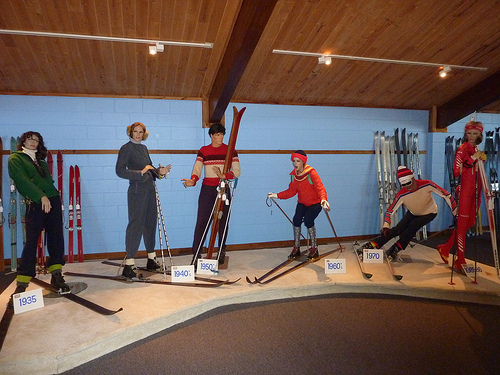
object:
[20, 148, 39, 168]
turtle neck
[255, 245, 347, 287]
skis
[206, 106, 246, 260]
skis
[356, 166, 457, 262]
mannequin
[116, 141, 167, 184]
one piece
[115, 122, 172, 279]
adult mannequin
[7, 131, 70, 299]
adult mannequin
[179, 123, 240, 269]
adult mannequin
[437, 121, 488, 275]
adult mannequin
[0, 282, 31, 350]
skis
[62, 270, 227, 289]
skis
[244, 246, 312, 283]
skis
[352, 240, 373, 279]
skis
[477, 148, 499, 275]
skis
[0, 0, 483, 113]
ceiling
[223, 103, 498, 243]
wall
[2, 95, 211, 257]
wall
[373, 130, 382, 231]
skis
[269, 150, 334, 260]
mannequin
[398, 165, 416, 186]
hat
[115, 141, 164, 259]
clothes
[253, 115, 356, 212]
block wall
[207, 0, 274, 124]
beam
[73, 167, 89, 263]
red ski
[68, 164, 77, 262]
red ski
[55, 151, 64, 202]
red ski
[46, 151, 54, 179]
red ski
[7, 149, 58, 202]
green fleece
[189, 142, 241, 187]
sweater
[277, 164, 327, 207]
jacket